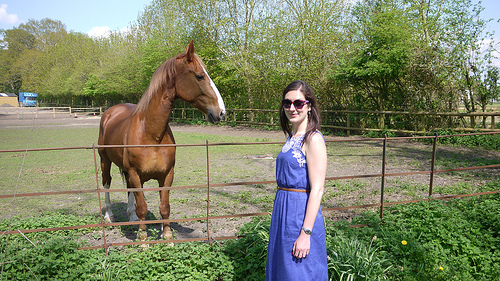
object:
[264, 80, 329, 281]
woman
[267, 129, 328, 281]
dress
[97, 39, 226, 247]
horse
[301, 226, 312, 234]
watch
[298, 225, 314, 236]
wrist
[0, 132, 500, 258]
fence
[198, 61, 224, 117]
white patch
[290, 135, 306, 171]
white pattern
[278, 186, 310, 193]
belt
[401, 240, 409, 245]
flower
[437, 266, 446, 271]
flower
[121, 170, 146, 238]
legs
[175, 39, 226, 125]
brown head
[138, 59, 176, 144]
neck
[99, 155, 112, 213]
leg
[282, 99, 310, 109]
sunglasses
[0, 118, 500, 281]
field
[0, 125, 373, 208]
grass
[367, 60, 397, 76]
leaves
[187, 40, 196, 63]
ear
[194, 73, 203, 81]
eye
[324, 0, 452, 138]
tree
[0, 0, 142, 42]
clouds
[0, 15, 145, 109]
trees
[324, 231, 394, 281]
bush